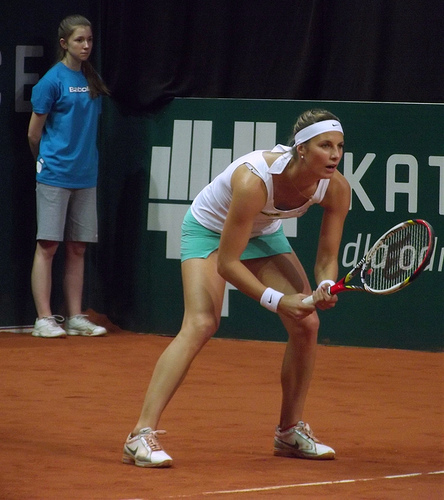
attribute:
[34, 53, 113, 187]
shirt — blue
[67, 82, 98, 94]
word — white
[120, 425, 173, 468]
shoe — white, nike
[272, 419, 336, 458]
shoe — white, nike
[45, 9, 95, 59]
hair — brown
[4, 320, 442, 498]
ground — red, dirt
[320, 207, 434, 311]
racket — white, red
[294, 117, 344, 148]
headband — white, nike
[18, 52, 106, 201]
shirt — blue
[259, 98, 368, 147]
head band — white, Nike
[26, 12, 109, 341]
girl — young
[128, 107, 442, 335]
advertising — white, green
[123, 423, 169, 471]
shoe — white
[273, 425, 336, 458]
shoe — white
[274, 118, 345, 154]
headband — white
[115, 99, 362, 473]
woman — bent over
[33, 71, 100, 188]
t-shirt — blue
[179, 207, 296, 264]
skirt — tourquoise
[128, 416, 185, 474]
shoe — white, pink, Nike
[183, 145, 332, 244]
tank — white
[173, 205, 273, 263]
skirt — aqua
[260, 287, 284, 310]
wrist band — nike, white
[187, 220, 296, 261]
tennis uniform — blue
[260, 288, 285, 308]
band — white, Nike